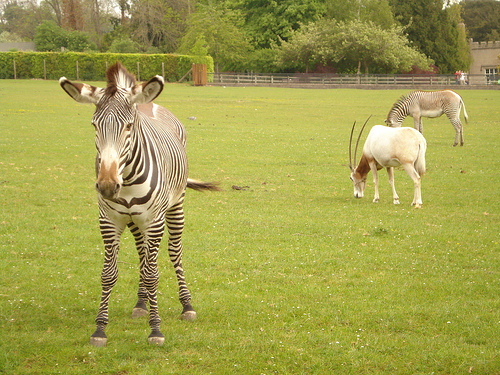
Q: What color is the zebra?
A: Black and white.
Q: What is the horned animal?
A: Gazelle.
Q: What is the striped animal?
A: Zebra.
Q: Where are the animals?
A: Zoo.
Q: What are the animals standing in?
A: Grass.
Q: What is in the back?
A: Fence.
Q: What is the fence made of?
A: Wood.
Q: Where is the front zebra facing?
A: Toward the camera.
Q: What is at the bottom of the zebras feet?
A: Hooves.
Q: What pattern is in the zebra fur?
A: Stripes.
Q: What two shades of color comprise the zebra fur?
A: Black and white.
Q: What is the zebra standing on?
A: Grass.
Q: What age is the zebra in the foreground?
A: Juvenile.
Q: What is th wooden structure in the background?
A: Fence.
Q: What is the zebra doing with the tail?
A: Wagging.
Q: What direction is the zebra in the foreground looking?
A: Straight ahead.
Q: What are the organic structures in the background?
A: Trees and foliage.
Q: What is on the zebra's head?
A: Mane.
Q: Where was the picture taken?
A: In a zoo.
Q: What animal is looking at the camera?
A: A zebra.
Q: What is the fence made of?
A: Wood.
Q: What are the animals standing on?
A: Grass.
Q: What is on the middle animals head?
A: Horns.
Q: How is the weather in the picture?
A: Sunny.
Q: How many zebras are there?
A: Two.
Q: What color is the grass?
A: Green.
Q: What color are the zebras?
A: Black and white.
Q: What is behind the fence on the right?
A: A building.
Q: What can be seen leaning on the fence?
A: People.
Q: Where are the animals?
A: In a field.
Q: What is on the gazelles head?
A: Horns.